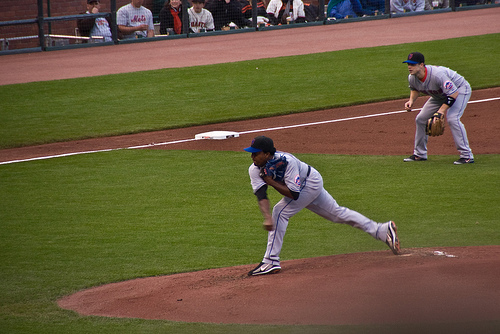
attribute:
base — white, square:
[195, 128, 238, 140]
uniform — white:
[249, 150, 389, 264]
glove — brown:
[423, 114, 446, 135]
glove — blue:
[257, 162, 290, 189]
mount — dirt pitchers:
[57, 253, 450, 315]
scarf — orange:
[163, 7, 184, 39]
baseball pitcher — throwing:
[219, 126, 439, 274]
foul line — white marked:
[17, 100, 490, 170]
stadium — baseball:
[12, 11, 462, 67]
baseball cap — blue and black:
[239, 133, 279, 157]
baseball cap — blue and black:
[402, 45, 427, 77]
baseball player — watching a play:
[396, 45, 483, 192]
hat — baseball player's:
[396, 46, 426, 71]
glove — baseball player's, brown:
[414, 114, 459, 137]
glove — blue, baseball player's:
[247, 156, 296, 195]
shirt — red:
[384, 58, 493, 110]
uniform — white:
[243, 162, 310, 198]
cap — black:
[245, 140, 277, 159]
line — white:
[18, 120, 499, 143]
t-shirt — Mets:
[118, 16, 151, 34]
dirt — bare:
[165, 271, 442, 308]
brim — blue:
[239, 147, 260, 161]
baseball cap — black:
[235, 131, 283, 165]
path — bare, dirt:
[2, 88, 484, 170]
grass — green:
[2, 31, 484, 146]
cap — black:
[236, 132, 281, 155]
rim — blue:
[241, 146, 261, 156]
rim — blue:
[399, 58, 419, 65]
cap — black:
[396, 46, 427, 68]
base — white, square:
[192, 127, 246, 143]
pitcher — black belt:
[239, 127, 406, 274]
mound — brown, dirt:
[53, 243, 483, 332]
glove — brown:
[422, 111, 449, 139]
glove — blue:
[256, 155, 290, 184]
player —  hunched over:
[232, 135, 409, 274]